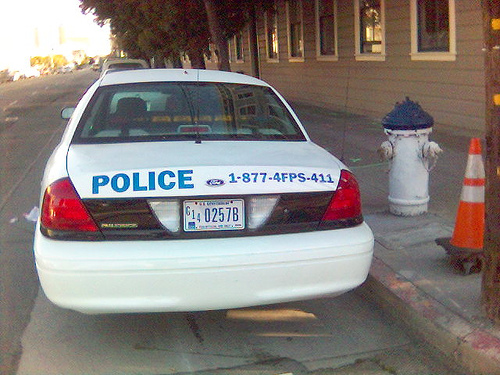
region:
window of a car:
[65, 67, 320, 155]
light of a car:
[34, 174, 109, 239]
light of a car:
[320, 161, 373, 229]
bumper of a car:
[20, 219, 383, 330]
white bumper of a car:
[43, 228, 383, 313]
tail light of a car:
[300, 141, 377, 238]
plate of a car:
[155, 162, 275, 249]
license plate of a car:
[171, 187, 273, 255]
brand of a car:
[200, 171, 238, 195]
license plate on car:
[180, 200, 247, 234]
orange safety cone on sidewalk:
[442, 155, 494, 257]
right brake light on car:
[331, 171, 367, 229]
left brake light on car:
[47, 180, 98, 239]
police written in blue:
[90, 171, 193, 192]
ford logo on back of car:
[202, 176, 229, 196]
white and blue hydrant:
[382, 88, 445, 219]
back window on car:
[103, 79, 279, 141]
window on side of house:
[349, 2, 395, 62]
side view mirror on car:
[54, 105, 76, 119]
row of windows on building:
[235, 2, 481, 111]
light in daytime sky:
[0, 2, 111, 76]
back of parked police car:
[36, 68, 372, 313]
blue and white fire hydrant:
[378, 97, 440, 218]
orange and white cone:
[438, 139, 485, 254]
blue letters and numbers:
[89, 168, 341, 193]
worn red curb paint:
[368, 266, 498, 368]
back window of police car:
[70, 80, 301, 145]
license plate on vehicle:
[183, 197, 247, 233]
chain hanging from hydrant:
[419, 153, 439, 173]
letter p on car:
[88, 174, 105, 193]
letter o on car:
[113, 171, 126, 193]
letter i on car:
[142, 165, 157, 194]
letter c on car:
[158, 167, 173, 191]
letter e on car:
[176, 167, 194, 192]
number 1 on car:
[226, 169, 235, 185]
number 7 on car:
[251, 170, 258, 182]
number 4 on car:
[273, 170, 282, 185]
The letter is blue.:
[86, 170, 109, 200]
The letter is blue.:
[107, 170, 133, 195]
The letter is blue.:
[130, 165, 149, 195]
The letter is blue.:
[143, 170, 158, 192]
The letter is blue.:
[156, 167, 178, 196]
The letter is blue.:
[176, 165, 198, 192]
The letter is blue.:
[281, 170, 291, 185]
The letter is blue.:
[288, 169, 298, 185]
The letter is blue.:
[295, 170, 309, 188]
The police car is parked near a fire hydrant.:
[33, 37, 457, 353]